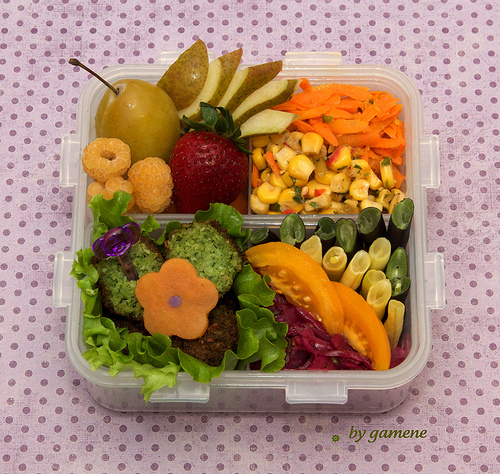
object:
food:
[83, 75, 412, 372]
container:
[53, 51, 446, 414]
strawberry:
[168, 101, 254, 215]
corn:
[250, 131, 406, 214]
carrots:
[251, 78, 405, 189]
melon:
[135, 257, 220, 340]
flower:
[68, 189, 289, 406]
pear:
[67, 39, 299, 159]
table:
[0, 0, 499, 473]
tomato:
[246, 240, 391, 370]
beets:
[244, 198, 416, 371]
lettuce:
[67, 188, 289, 406]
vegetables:
[69, 190, 288, 404]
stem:
[180, 101, 253, 155]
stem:
[69, 57, 118, 95]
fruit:
[68, 40, 298, 214]